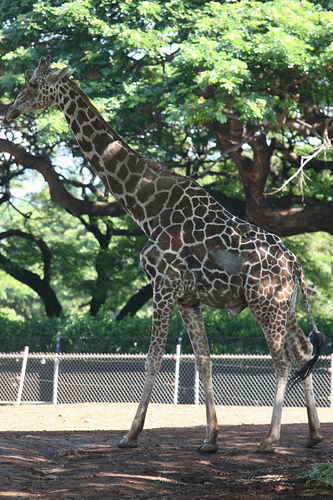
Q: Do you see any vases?
A: No, there are no vases.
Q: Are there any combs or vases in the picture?
A: No, there are no vases or combs.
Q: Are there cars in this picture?
A: No, there are no cars.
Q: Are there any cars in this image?
A: No, there are no cars.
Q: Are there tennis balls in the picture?
A: No, there are no tennis balls.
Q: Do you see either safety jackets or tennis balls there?
A: No, there are no tennis balls or safety jackets.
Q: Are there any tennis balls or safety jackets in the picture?
A: No, there are no tennis balls or safety jackets.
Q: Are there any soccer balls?
A: No, there are no soccer balls.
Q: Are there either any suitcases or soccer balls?
A: No, there are no soccer balls or suitcases.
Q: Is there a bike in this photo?
A: No, there are no bikes.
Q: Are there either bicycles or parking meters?
A: No, there are no bicycles or parking meters.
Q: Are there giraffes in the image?
A: Yes, there is a giraffe.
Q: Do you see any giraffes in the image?
A: Yes, there is a giraffe.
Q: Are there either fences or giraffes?
A: Yes, there is a giraffe.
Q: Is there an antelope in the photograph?
A: No, there are no antelopes.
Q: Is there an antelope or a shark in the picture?
A: No, there are no antelopes or sharks.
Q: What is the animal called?
A: The animal is a giraffe.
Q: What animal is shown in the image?
A: The animal is a giraffe.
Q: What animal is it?
A: The animal is a giraffe.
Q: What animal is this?
A: This is a giraffe.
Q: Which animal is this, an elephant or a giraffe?
A: This is a giraffe.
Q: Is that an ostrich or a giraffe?
A: That is a giraffe.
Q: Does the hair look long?
A: Yes, the hair is long.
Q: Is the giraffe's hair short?
A: No, the hair is long.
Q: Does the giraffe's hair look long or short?
A: The hair is long.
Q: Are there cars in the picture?
A: No, there are no cars.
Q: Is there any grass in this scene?
A: Yes, there is grass.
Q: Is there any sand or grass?
A: Yes, there is grass.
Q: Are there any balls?
A: No, there are no balls.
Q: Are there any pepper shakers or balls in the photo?
A: No, there are no balls or pepper shakers.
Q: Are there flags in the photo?
A: No, there are no flags.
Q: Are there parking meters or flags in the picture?
A: No, there are no flags or parking meters.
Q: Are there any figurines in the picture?
A: No, there are no figurines.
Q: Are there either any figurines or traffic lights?
A: No, there are no figurines or traffic lights.